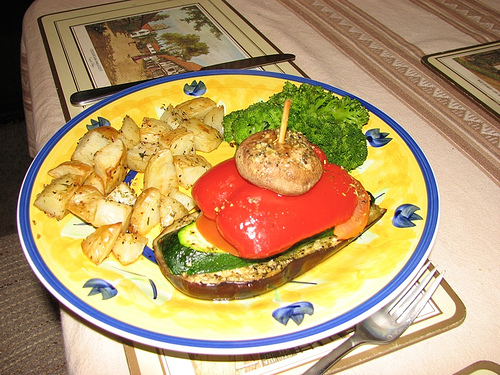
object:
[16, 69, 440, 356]
plate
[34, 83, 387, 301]
meal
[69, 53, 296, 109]
knife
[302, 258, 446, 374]
fork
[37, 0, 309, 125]
placemat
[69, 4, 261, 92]
picture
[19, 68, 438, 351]
border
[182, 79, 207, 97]
flower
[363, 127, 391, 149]
flower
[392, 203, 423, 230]
flower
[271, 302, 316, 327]
flower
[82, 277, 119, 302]
flower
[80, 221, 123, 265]
potatoes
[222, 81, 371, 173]
broccoli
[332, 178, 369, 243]
tomato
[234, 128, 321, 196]
mushroom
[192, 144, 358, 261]
pepper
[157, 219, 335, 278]
zucchini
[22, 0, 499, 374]
tablecloth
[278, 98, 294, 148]
stick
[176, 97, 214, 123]
potato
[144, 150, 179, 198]
potato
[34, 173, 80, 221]
potato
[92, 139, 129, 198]
potato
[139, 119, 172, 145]
potato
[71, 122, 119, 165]
potato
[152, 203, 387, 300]
eggplant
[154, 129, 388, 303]
sandwich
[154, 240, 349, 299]
edge